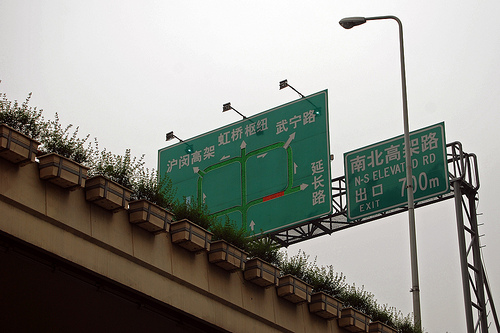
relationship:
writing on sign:
[159, 107, 316, 173] [153, 90, 333, 233]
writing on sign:
[349, 130, 439, 171] [342, 120, 449, 220]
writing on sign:
[352, 154, 435, 190] [342, 120, 449, 220]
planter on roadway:
[0, 121, 40, 169] [0, 130, 415, 332]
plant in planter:
[0, 84, 44, 135] [0, 121, 40, 169]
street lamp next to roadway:
[338, 14, 425, 332] [0, 130, 415, 332]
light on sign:
[309, 103, 325, 118] [153, 90, 333, 233]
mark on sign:
[261, 189, 285, 203] [153, 90, 333, 233]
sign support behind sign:
[264, 141, 498, 332] [153, 90, 333, 233]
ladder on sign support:
[448, 139, 498, 333] [264, 141, 498, 332]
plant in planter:
[42, 112, 94, 163] [35, 151, 91, 190]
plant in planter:
[90, 145, 145, 189] [84, 175, 134, 213]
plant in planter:
[134, 167, 180, 211] [129, 199, 173, 237]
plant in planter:
[173, 194, 217, 229] [172, 217, 216, 252]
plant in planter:
[214, 218, 253, 251] [208, 237, 249, 274]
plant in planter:
[249, 228, 285, 265] [244, 257, 281, 289]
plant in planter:
[282, 250, 317, 282] [276, 274, 313, 306]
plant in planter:
[312, 264, 347, 296] [310, 287, 345, 320]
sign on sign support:
[342, 120, 449, 220] [264, 141, 498, 332]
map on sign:
[190, 133, 305, 235] [153, 90, 333, 233]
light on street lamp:
[338, 14, 367, 31] [338, 14, 425, 332]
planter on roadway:
[35, 151, 91, 190] [0, 130, 415, 332]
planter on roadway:
[84, 175, 134, 213] [0, 130, 415, 332]